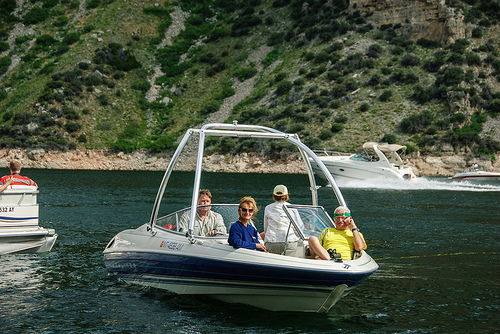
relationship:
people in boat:
[162, 149, 351, 277] [81, 136, 420, 315]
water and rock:
[80, 174, 141, 231] [117, 146, 140, 165]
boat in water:
[81, 136, 420, 315] [80, 174, 141, 231]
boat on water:
[81, 136, 420, 315] [80, 174, 141, 231]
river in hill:
[28, 162, 124, 226] [260, 40, 391, 124]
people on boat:
[162, 149, 351, 277] [81, 136, 420, 315]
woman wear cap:
[225, 188, 266, 257] [268, 186, 298, 194]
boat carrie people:
[81, 136, 420, 315] [162, 149, 351, 277]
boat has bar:
[81, 136, 420, 315] [213, 225, 254, 254]